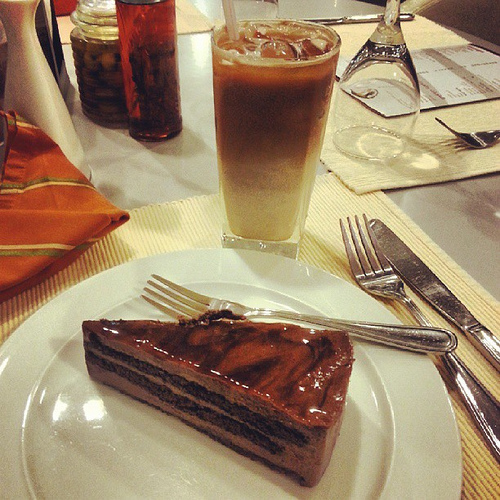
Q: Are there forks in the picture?
A: Yes, there is a fork.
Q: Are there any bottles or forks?
A: Yes, there is a fork.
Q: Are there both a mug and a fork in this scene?
A: No, there is a fork but no mugs.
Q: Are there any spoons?
A: No, there are no spoons.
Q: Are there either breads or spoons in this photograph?
A: No, there are no spoons or breads.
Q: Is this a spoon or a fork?
A: This is a fork.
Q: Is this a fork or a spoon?
A: This is a fork.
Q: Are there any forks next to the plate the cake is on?
A: Yes, there is a fork next to the plate.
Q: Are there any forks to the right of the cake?
A: Yes, there is a fork to the right of the cake.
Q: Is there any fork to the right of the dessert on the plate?
A: Yes, there is a fork to the right of the cake.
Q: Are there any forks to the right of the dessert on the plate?
A: Yes, there is a fork to the right of the cake.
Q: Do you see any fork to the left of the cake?
A: No, the fork is to the right of the cake.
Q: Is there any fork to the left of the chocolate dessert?
A: No, the fork is to the right of the cake.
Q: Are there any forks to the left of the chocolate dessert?
A: No, the fork is to the right of the cake.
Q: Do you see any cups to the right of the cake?
A: No, there is a fork to the right of the cake.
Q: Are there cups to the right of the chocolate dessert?
A: No, there is a fork to the right of the cake.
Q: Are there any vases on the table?
A: No, there is a fork on the table.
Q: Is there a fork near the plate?
A: Yes, there is a fork near the plate.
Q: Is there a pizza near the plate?
A: No, there is a fork near the plate.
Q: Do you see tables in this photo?
A: Yes, there is a table.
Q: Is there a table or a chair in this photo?
A: Yes, there is a table.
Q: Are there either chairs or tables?
A: Yes, there is a table.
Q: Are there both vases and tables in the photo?
A: No, there is a table but no vases.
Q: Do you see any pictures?
A: No, there are no pictures.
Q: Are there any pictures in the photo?
A: No, there are no pictures.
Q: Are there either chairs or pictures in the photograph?
A: No, there are no pictures or chairs.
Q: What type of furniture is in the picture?
A: The furniture is a table.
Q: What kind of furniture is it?
A: The piece of furniture is a table.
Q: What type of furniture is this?
A: That is a table.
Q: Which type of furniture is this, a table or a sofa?
A: That is a table.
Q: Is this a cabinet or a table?
A: This is a table.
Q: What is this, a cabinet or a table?
A: This is a table.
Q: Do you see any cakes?
A: Yes, there is a cake.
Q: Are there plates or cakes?
A: Yes, there is a cake.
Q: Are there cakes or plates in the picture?
A: Yes, there is a cake.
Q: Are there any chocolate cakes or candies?
A: Yes, there is a chocolate cake.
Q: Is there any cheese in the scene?
A: No, there is no cheese.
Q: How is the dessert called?
A: The dessert is a cake.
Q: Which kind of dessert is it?
A: The dessert is a cake.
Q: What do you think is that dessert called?
A: This is a cake.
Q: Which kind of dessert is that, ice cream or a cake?
A: This is a cake.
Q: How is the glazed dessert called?
A: The dessert is a cake.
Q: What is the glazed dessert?
A: The dessert is a cake.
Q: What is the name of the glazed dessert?
A: The dessert is a cake.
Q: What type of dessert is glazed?
A: The dessert is a cake.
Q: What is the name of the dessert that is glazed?
A: The dessert is a cake.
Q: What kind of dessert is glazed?
A: The dessert is a cake.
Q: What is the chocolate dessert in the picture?
A: The dessert is a cake.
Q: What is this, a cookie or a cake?
A: This is a cake.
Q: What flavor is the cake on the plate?
A: This is a chocolate cake.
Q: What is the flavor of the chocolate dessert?
A: This is a chocolate cake.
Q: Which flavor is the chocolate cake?
A: This is a chocolate cake.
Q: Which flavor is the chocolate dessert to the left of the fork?
A: This is a chocolate cake.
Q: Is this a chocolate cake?
A: Yes, this is a chocolate cake.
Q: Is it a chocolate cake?
A: Yes, this is a chocolate cake.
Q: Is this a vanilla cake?
A: No, this is a chocolate cake.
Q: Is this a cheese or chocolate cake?
A: This is a chocolate cake.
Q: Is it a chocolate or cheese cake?
A: This is a chocolate cake.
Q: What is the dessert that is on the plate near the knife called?
A: The dessert is a cake.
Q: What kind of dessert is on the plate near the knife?
A: The dessert is a cake.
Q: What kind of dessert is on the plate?
A: The dessert is a cake.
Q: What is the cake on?
A: The cake is on the plate.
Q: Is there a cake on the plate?
A: Yes, there is a cake on the plate.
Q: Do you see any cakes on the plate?
A: Yes, there is a cake on the plate.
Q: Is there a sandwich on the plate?
A: No, there is a cake on the plate.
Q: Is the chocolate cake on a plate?
A: Yes, the cake is on a plate.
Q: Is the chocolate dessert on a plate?
A: Yes, the cake is on a plate.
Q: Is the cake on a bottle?
A: No, the cake is on a plate.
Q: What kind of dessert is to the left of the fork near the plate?
A: The dessert is a cake.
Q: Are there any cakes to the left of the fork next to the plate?
A: Yes, there is a cake to the left of the fork.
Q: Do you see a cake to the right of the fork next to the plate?
A: No, the cake is to the left of the fork.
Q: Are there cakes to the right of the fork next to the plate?
A: No, the cake is to the left of the fork.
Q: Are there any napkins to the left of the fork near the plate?
A: No, there is a cake to the left of the fork.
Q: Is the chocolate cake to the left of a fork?
A: Yes, the cake is to the left of a fork.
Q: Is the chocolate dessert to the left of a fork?
A: Yes, the cake is to the left of a fork.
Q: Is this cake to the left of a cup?
A: No, the cake is to the left of a fork.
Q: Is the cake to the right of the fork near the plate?
A: No, the cake is to the left of the fork.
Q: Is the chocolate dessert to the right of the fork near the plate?
A: No, the cake is to the left of the fork.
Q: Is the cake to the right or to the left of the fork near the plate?
A: The cake is to the left of the fork.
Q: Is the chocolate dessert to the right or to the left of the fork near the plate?
A: The cake is to the left of the fork.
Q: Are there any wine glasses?
A: Yes, there is a wine glass.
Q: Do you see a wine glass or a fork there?
A: Yes, there is a wine glass.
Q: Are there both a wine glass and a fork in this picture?
A: Yes, there are both a wine glass and a fork.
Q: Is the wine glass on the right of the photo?
A: Yes, the wine glass is on the right of the image.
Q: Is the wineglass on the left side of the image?
A: No, the wineglass is on the right of the image.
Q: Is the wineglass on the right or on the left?
A: The wineglass is on the right of the image.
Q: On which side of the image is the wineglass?
A: The wineglass is on the right of the image.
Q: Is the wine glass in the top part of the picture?
A: Yes, the wine glass is in the top of the image.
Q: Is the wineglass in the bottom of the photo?
A: No, the wineglass is in the top of the image.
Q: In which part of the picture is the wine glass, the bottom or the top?
A: The wine glass is in the top of the image.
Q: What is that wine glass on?
A: The wine glass is on the table.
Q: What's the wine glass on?
A: The wine glass is on the table.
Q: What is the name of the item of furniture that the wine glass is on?
A: The piece of furniture is a table.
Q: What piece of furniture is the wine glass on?
A: The wine glass is on the table.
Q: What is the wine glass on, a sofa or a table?
A: The wine glass is on a table.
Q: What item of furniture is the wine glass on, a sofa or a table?
A: The wine glass is on a table.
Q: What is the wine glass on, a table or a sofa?
A: The wine glass is on a table.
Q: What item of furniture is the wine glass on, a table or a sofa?
A: The wine glass is on a table.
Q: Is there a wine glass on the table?
A: Yes, there is a wine glass on the table.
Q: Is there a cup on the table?
A: No, there is a wine glass on the table.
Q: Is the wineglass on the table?
A: Yes, the wineglass is on the table.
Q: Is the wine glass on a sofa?
A: No, the wine glass is on the table.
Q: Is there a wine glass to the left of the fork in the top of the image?
A: Yes, there is a wine glass to the left of the fork.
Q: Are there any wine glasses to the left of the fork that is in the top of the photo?
A: Yes, there is a wine glass to the left of the fork.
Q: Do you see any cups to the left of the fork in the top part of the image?
A: No, there is a wine glass to the left of the fork.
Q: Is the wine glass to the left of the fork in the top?
A: Yes, the wine glass is to the left of the fork.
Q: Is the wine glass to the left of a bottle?
A: No, the wine glass is to the left of the fork.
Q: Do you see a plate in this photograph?
A: Yes, there is a plate.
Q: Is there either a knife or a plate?
A: Yes, there is a plate.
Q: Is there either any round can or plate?
A: Yes, there is a round plate.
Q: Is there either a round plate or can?
A: Yes, there is a round plate.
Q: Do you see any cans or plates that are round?
A: Yes, the plate is round.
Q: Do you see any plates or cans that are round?
A: Yes, the plate is round.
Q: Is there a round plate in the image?
A: Yes, there is a round plate.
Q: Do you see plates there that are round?
A: Yes, there is a plate that is round.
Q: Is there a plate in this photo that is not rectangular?
A: Yes, there is a round plate.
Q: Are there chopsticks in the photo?
A: No, there are no chopsticks.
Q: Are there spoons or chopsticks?
A: No, there are no chopsticks or spoons.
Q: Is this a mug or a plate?
A: This is a plate.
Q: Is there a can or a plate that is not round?
A: No, there is a plate but it is round.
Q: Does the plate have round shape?
A: Yes, the plate is round.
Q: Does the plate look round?
A: Yes, the plate is round.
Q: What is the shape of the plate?
A: The plate is round.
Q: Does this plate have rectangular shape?
A: No, the plate is round.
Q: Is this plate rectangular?
A: No, the plate is round.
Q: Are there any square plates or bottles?
A: No, there is a plate but it is round.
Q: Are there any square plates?
A: No, there is a plate but it is round.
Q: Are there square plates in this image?
A: No, there is a plate but it is round.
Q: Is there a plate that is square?
A: No, there is a plate but it is round.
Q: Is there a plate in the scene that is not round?
A: No, there is a plate but it is round.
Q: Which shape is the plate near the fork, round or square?
A: The plate is round.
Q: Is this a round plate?
A: Yes, this is a round plate.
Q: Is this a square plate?
A: No, this is a round plate.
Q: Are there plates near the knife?
A: Yes, there is a plate near the knife.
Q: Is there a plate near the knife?
A: Yes, there is a plate near the knife.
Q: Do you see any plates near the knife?
A: Yes, there is a plate near the knife.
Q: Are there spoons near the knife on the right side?
A: No, there is a plate near the knife.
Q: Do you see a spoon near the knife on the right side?
A: No, there is a plate near the knife.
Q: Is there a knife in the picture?
A: Yes, there is a knife.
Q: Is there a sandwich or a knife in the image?
A: Yes, there is a knife.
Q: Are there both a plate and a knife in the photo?
A: Yes, there are both a knife and a plate.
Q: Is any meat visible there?
A: No, there is no meat.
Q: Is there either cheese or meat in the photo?
A: No, there are no meat or cheese.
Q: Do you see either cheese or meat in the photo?
A: No, there are no meat or cheese.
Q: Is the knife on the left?
A: No, the knife is on the right of the image.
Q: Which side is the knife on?
A: The knife is on the right of the image.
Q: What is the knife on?
A: The knife is on the table.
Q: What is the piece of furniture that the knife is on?
A: The piece of furniture is a table.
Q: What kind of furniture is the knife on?
A: The knife is on the table.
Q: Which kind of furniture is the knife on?
A: The knife is on the table.